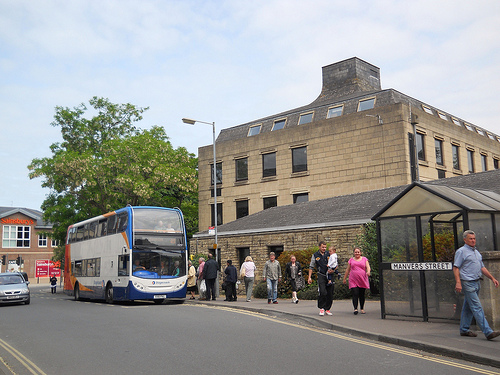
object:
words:
[0, 218, 34, 225]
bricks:
[343, 125, 386, 176]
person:
[264, 252, 282, 304]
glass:
[378, 215, 428, 320]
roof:
[414, 180, 500, 212]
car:
[0, 271, 31, 305]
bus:
[63, 205, 187, 304]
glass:
[132, 233, 187, 277]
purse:
[200, 279, 207, 292]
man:
[308, 240, 334, 316]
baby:
[327, 245, 342, 287]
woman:
[343, 247, 371, 314]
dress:
[347, 256, 370, 289]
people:
[187, 251, 302, 304]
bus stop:
[369, 182, 500, 332]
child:
[325, 244, 338, 287]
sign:
[143, 238, 175, 244]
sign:
[36, 259, 61, 276]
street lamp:
[181, 118, 214, 126]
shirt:
[453, 243, 482, 281]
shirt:
[348, 256, 370, 289]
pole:
[212, 122, 219, 299]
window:
[235, 156, 249, 181]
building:
[191, 57, 500, 295]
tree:
[29, 96, 198, 272]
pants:
[350, 286, 366, 309]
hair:
[463, 230, 476, 238]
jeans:
[457, 279, 494, 338]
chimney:
[320, 57, 382, 95]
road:
[0, 304, 497, 375]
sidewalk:
[323, 315, 359, 338]